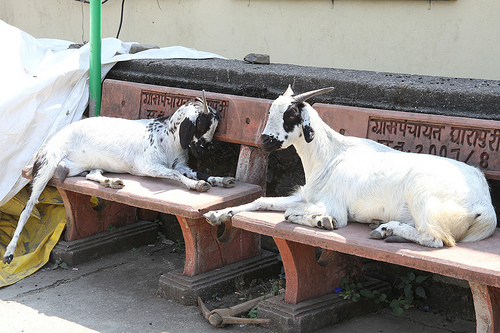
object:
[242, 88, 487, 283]
goat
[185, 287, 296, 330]
axe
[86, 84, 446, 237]
goats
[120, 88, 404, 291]
benches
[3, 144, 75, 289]
tarp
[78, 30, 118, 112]
pole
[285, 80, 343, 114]
antler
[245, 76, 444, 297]
goat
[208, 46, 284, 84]
rock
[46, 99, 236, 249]
goat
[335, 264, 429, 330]
weeds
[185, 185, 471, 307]
bench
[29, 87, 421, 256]
goats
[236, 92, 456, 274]
goats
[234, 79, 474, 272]
goats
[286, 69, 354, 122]
horn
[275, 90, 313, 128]
eye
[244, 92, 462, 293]
goat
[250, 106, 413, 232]
goat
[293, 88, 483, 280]
goat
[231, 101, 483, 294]
goat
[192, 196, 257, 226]
hoof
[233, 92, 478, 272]
goat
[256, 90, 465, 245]
goat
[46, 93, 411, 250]
goats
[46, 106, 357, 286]
benches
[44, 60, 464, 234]
goats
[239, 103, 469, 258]
goats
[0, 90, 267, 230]
goats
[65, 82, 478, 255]
goats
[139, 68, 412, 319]
bench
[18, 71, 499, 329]
bench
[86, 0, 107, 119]
pole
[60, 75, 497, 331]
bench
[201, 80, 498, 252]
goat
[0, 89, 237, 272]
goat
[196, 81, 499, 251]
animal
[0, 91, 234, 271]
animal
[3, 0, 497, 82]
wall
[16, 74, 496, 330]
benches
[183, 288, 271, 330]
ax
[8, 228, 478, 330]
floor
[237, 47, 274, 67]
rock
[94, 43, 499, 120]
wall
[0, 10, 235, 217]
tarp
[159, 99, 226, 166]
face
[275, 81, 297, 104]
horn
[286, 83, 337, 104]
horn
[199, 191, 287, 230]
leg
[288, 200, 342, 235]
leg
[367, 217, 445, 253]
leg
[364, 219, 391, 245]
leg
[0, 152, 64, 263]
leg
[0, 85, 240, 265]
cabro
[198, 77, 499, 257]
cabro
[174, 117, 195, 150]
spots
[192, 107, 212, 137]
spots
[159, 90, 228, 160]
head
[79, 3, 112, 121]
bar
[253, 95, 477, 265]
goat